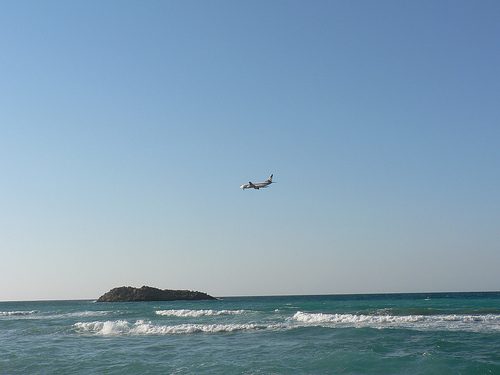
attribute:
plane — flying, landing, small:
[238, 174, 276, 190]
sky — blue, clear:
[0, 0, 499, 301]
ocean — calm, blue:
[0, 291, 500, 374]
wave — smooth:
[71, 309, 500, 338]